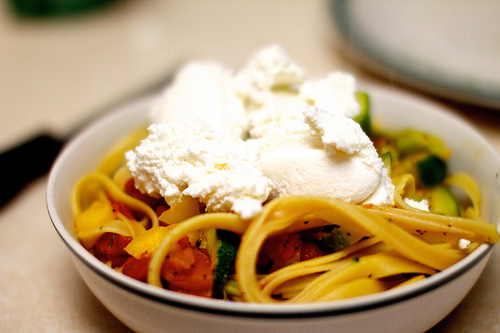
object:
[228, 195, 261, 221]
cheese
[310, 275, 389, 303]
pasta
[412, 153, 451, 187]
broccoli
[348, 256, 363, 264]
flecks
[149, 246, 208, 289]
tomato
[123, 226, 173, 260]
yellow peppers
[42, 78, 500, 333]
bowl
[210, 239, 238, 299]
vegetables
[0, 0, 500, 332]
background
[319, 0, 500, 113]
plate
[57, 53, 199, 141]
knife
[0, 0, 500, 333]
counter top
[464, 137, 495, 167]
sauce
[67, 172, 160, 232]
stripe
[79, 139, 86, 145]
edge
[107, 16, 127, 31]
part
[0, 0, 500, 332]
table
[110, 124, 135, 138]
inside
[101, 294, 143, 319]
side